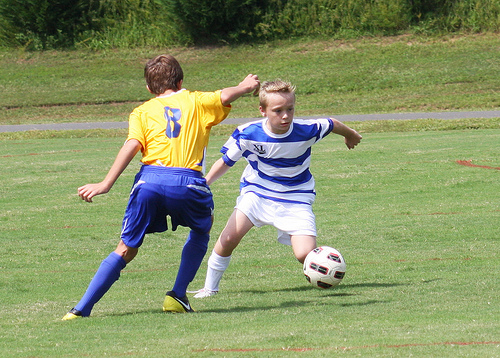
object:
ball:
[300, 243, 349, 291]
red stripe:
[191, 339, 500, 353]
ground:
[0, 32, 500, 358]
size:
[250, 142, 268, 157]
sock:
[204, 250, 231, 293]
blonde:
[253, 75, 298, 113]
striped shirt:
[217, 116, 336, 207]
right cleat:
[169, 309, 177, 315]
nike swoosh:
[172, 296, 194, 312]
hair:
[142, 52, 185, 98]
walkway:
[0, 105, 499, 136]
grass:
[0, 117, 499, 357]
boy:
[190, 77, 364, 301]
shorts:
[232, 188, 318, 247]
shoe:
[161, 288, 196, 314]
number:
[163, 106, 183, 140]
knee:
[219, 229, 241, 248]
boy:
[58, 51, 261, 322]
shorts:
[118, 163, 216, 249]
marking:
[453, 157, 500, 172]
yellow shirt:
[125, 87, 233, 171]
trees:
[1, 0, 500, 52]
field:
[0, 29, 499, 357]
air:
[365, 174, 453, 311]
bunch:
[0, 0, 499, 54]